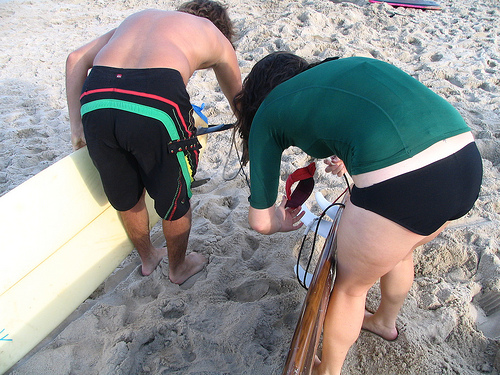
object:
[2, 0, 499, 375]
sand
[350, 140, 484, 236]
bottoms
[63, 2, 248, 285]
man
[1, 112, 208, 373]
surfboard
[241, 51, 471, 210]
green shirt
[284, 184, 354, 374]
surfboard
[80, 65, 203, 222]
bottoms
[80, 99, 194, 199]
stripes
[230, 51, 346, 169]
down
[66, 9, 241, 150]
no shirt on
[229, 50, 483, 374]
people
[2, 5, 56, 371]
left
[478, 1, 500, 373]
right